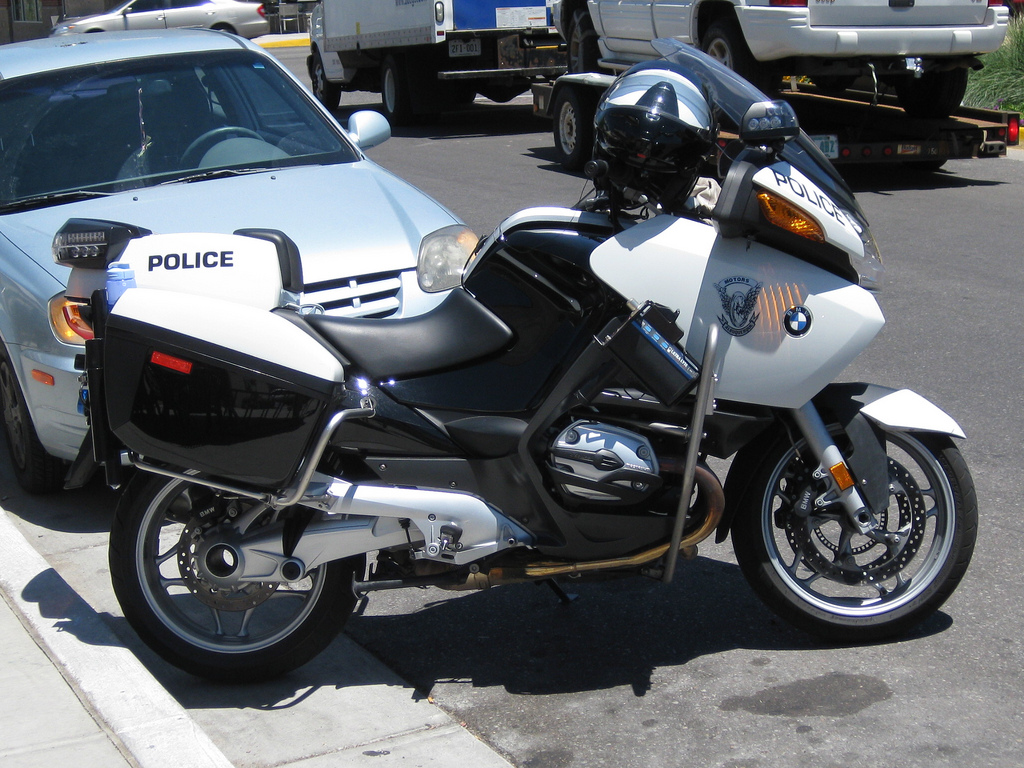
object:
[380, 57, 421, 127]
wheel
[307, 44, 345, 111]
wheel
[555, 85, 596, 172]
wheel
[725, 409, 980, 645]
wheel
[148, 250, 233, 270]
text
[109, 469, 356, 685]
tire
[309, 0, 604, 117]
vehicle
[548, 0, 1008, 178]
vehicle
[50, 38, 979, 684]
vehicle